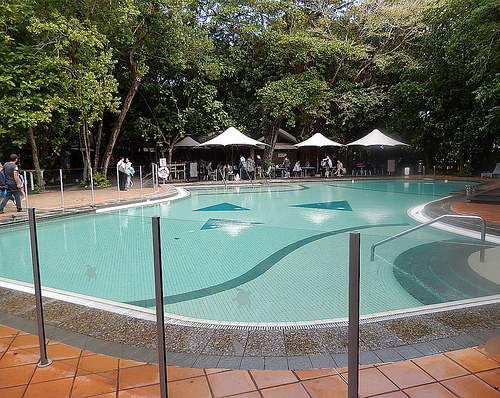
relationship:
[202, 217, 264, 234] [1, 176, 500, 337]
triangles on bottom of pool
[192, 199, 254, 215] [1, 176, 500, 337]
triangles on bottom of pool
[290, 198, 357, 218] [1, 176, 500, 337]
triangles on bottom of pool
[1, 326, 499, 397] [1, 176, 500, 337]
tiles are brown around pool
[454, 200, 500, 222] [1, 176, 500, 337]
tiles are brown around pool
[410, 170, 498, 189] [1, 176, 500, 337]
tiles are brown around pool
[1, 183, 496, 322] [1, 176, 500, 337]
water blue in pool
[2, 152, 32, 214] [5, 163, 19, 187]
man wearing a grey shirt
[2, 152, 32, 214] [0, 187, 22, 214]
man wearing grey jeans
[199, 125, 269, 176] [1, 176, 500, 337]
umbrella near pool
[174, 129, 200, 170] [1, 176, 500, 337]
umbrella near pool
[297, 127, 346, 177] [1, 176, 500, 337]
umbrella near pool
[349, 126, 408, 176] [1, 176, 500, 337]
umbrella near pool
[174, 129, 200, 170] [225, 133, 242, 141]
umbrella color white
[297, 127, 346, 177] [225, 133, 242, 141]
umbrella color white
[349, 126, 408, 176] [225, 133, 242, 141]
umbrella color white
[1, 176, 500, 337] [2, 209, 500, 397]
pool has a glass fence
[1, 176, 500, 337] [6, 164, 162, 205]
pool has a glass fence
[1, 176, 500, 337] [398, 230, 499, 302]
pool has steps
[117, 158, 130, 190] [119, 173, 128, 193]
man wearing black pants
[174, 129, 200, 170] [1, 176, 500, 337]
umbrella by pool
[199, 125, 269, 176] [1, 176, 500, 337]
umbrella by pool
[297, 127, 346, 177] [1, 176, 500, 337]
umbrella by pool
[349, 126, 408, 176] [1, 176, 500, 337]
umbrella by pool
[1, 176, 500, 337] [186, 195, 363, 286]
pool for swimming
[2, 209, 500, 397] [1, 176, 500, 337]
fence enclosing pool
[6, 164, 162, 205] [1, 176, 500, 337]
fence enclosing pool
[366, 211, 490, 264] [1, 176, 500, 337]
handrail in pool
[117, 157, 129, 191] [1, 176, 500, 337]
man near pool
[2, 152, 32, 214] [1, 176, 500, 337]
people near pool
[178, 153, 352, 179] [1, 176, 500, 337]
people near pool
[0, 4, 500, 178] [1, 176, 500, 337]
trees around pool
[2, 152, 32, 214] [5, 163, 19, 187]
man wearing a black shirt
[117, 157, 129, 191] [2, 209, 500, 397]
man by pool fence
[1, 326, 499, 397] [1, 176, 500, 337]
tiles in front of pool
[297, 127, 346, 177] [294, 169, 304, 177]
umbrella over tables and chairs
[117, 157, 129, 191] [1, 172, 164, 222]
man on sidewalk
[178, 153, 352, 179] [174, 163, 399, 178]
people sitting at tables and chairs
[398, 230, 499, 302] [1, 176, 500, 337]
steps going into pool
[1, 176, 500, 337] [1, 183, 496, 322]
pool filled with clear water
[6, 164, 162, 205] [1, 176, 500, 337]
fence made of glass around pool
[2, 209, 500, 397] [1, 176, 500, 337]
fence made of glass around pool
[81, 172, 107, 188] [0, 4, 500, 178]
plants near base of trees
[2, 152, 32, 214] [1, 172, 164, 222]
man walking on sidewalk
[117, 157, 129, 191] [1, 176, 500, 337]
man near swimming pool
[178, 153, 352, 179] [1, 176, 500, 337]
people near swimming pool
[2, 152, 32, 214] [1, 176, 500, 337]
person near pool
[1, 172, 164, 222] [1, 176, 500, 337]
sidewalk near pool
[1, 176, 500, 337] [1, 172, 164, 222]
pool has a smooth sidewalk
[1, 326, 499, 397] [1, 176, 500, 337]
tiles are smooth around pool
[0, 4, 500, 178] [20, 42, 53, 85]
trees have leaves that are green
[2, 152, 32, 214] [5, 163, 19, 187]
man wearing a shirt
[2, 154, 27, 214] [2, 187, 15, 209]
man wearing jeans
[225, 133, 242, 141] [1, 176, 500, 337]
white umbrellas near pool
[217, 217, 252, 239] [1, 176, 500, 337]
reflections in water of pool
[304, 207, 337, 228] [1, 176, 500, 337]
reflections in water of pool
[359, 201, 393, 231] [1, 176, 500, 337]
reflections in water of pool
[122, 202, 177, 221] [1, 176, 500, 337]
reflections in water of pool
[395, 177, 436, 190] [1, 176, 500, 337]
reflections in water of pool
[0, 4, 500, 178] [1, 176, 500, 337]
trees near swimming pool